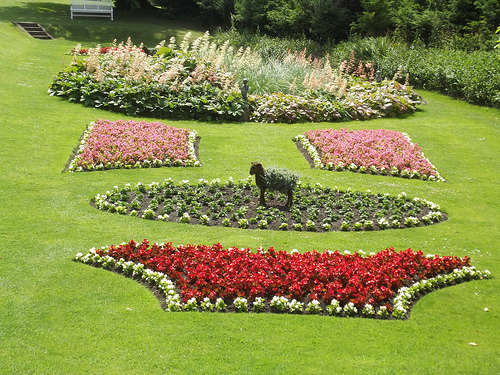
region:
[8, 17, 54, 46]
cement steps on the grass hill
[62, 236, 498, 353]
the plants in the dirt planter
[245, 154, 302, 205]
the sheep statue in the middle of the dirt patch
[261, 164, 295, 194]
the bush on the sheep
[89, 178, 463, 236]
the round patch of flowers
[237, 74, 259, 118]
a statue in the plants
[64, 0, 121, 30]
the white bench on the hill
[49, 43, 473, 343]
the gardens in the middle of the grass field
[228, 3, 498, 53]
the trees behind the yard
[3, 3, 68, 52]
the trees shadow on the grass hill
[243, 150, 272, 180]
Animal has brown head.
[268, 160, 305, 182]
Animal has gray body.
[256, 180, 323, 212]
Animal has dark legs.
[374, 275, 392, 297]
Red flowers planted in ground.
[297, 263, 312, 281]
Red flowers planted in ground.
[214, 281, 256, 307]
Red flowers planted in ground.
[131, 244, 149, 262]
Red flowers planted in ground.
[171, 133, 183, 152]
Pink flowers planted in ground.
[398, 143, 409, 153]
Pink flowers planted in ground.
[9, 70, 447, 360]
Green grass around flowers.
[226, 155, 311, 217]
sheep in the middle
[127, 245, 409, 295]
red flowers in a row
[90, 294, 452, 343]
white flowers outling the red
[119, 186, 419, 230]
green flowers in a circle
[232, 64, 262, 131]
statue in the middle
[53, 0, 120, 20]
bench in the back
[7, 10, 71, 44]
stairs leading to bench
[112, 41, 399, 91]
white flowers in the background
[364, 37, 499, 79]
green shrubery in the corner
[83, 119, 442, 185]
two flowers beds of pink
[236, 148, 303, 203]
animal looking object with green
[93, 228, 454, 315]
odd shaped red flower patch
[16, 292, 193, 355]
nice green maintaned grass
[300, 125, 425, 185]
square patch of pink flowers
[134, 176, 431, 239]
circular patch of vegetation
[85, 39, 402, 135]
Large uncumbersome patch of wildlife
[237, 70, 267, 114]
statue of small person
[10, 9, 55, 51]
small grate in the ground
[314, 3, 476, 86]
green trees/bushes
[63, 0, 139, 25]
small white park bench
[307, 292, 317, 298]
red flower is next to red flower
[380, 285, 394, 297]
red flower is next to red flower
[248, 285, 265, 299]
red flower is next to red flower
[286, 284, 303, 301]
red flower is next to red flower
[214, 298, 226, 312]
white flower is next to white flower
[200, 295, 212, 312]
white flower is next to white flower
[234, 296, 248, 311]
white flower is next to white flower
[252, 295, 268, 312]
white flower is next to white flower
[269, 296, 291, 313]
white flower is next to white flower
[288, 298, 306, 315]
white flower is next to white flower